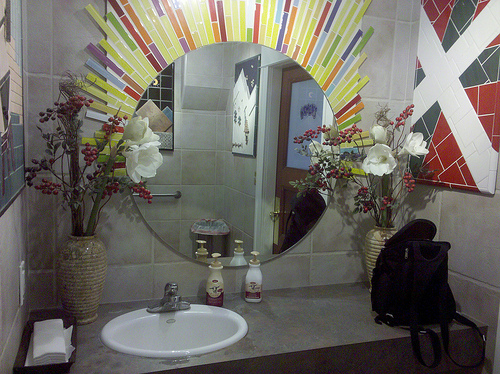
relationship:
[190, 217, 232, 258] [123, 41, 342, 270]
trash can showing in mirror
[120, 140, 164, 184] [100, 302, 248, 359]
flower near sink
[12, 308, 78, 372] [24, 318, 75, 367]
rack holding paper towels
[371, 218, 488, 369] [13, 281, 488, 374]
bag sitting on counter top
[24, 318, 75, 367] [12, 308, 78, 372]
paper towels sitting in rack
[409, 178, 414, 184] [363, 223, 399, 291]
cherry inside of vase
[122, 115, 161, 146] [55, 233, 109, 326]
flower sitting in vase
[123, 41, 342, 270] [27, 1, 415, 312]
mirror hanging on wall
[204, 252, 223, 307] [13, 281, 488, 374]
soap sitting on counter top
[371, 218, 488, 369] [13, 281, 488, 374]
bag laying on counter top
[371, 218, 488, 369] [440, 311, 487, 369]
bag has strap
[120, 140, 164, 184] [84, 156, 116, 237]
flower on end of stem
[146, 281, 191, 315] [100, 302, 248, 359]
faucet over sink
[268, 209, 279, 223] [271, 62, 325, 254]
door handle on side of door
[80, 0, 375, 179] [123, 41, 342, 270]
decoration above mirror